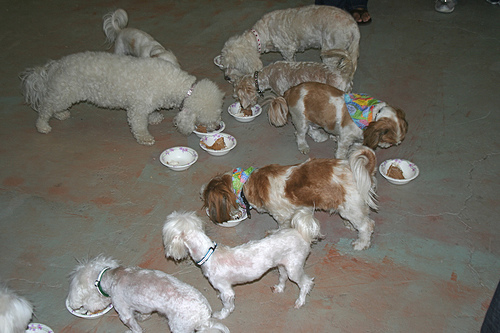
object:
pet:
[21, 49, 224, 145]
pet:
[201, 146, 379, 250]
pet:
[62, 256, 229, 333]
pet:
[231, 60, 354, 110]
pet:
[268, 84, 409, 163]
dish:
[157, 145, 201, 172]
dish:
[200, 132, 235, 155]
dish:
[377, 157, 420, 185]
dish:
[227, 99, 264, 122]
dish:
[189, 121, 227, 139]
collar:
[175, 78, 200, 114]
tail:
[21, 63, 56, 112]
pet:
[100, 7, 179, 69]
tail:
[99, 7, 127, 45]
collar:
[253, 69, 264, 98]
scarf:
[340, 91, 389, 128]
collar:
[96, 264, 109, 300]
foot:
[352, 8, 370, 23]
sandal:
[350, 7, 372, 23]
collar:
[193, 239, 215, 267]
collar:
[247, 26, 266, 56]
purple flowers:
[179, 146, 192, 154]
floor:
[1, 0, 499, 332]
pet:
[218, 6, 361, 78]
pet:
[159, 210, 309, 318]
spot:
[363, 145, 378, 184]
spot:
[287, 159, 344, 210]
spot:
[336, 170, 350, 183]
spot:
[243, 163, 288, 212]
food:
[201, 137, 224, 150]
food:
[385, 163, 406, 179]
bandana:
[226, 165, 250, 209]